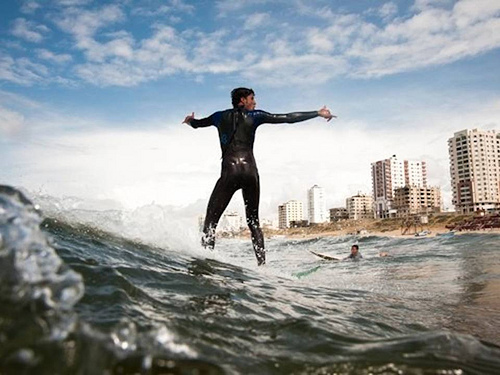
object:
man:
[179, 84, 340, 268]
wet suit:
[196, 111, 275, 257]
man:
[340, 244, 364, 263]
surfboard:
[308, 245, 341, 265]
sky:
[0, 3, 191, 111]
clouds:
[351, 22, 448, 83]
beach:
[290, 213, 490, 239]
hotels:
[306, 183, 331, 225]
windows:
[456, 146, 462, 151]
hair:
[229, 86, 255, 100]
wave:
[3, 200, 187, 277]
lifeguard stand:
[398, 212, 433, 238]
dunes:
[303, 219, 367, 235]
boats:
[414, 227, 433, 239]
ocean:
[2, 268, 498, 373]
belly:
[351, 256, 359, 260]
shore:
[268, 224, 489, 234]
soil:
[355, 223, 366, 228]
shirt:
[346, 252, 362, 262]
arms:
[261, 107, 323, 127]